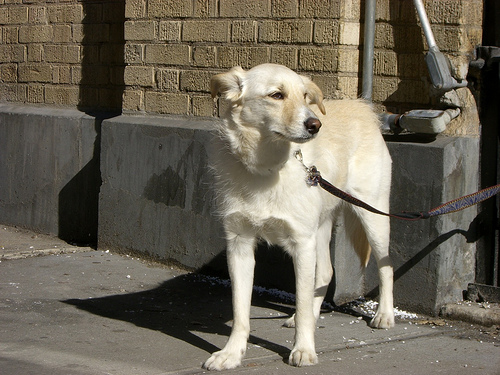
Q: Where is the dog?
A: On the leash.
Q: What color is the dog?
A: White.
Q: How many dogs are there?
A: 1.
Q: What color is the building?
A: Tan.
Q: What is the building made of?
A: Bricks.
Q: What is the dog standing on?
A: Sidewalk.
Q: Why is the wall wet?
A: Dog peed on it.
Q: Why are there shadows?
A: Sunny.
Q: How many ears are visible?
A: 2.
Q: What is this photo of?
A: Dog.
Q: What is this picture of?
A: Dog standing on sidewalk.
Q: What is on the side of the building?
A: Electrical pipes.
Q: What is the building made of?
A: Bricks.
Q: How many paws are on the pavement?
A: 4.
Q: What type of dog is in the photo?
A: A mix breed.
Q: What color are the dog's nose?
A: Brown and black.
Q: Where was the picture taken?
A: On a sidewalk.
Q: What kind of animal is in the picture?
A: A dog.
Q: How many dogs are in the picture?
A: 1.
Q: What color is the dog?
A: White.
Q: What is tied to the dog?
A: A leash.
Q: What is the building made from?
A: Brick.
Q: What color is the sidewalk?
A: Gray.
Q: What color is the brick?
A: Brown.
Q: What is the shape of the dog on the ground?
A: A shadow.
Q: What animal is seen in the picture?
A: Dog.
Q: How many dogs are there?
A: 1.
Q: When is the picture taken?
A: Daytime.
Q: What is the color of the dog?
A: White and brown.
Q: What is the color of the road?
A: Grey.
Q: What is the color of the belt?
A: Black.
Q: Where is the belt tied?
A: To the neck of the dog.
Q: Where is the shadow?
A: In the ground.